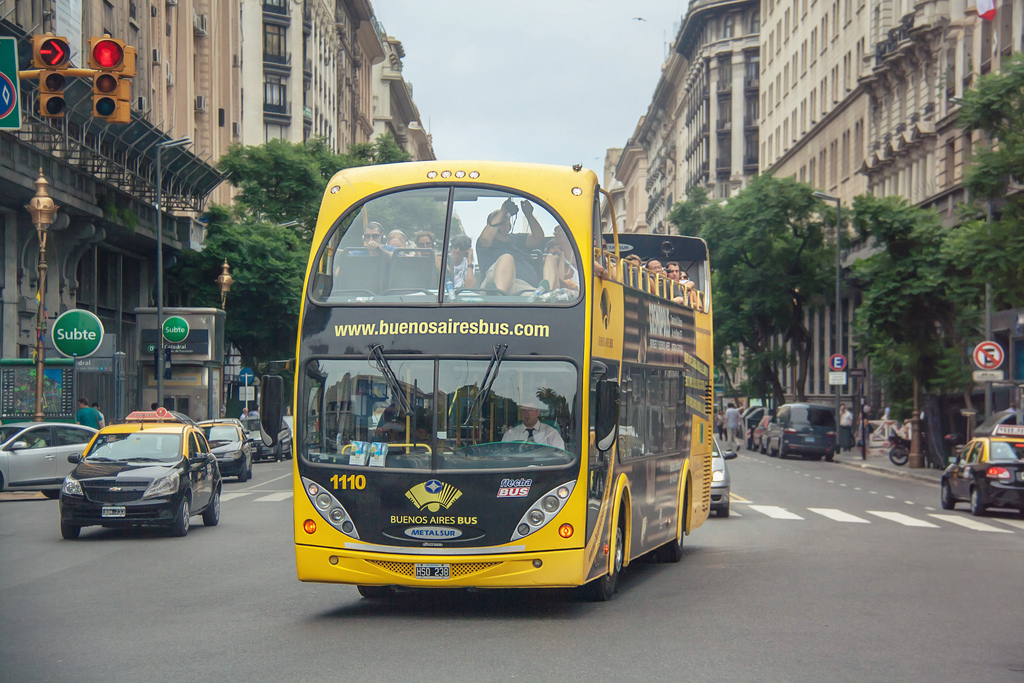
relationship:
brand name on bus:
[328, 315, 554, 345] [274, 145, 723, 621]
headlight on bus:
[511, 479, 578, 536] [274, 145, 723, 621]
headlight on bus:
[287, 472, 368, 548] [274, 145, 723, 621]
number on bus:
[330, 474, 366, 489] [274, 145, 723, 621]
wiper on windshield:
[473, 340, 504, 464] [357, 321, 431, 443]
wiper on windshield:
[356, 332, 421, 460] [357, 321, 431, 443]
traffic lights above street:
[15, 17, 134, 122] [1, 436, 1019, 668]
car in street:
[34, 425, 230, 550] [34, 425, 230, 667]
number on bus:
[312, 466, 420, 518] [312, 194, 657, 518]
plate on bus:
[324, 475, 528, 606] [324, 200, 604, 606]